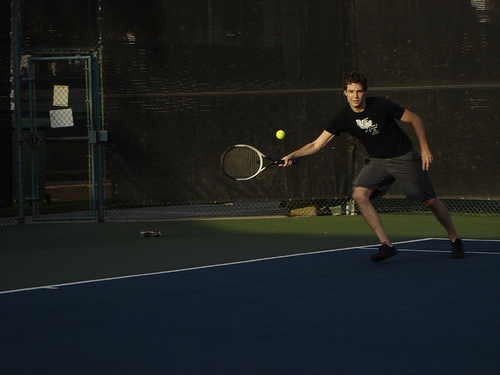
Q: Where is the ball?
A: In the air.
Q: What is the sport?
A: Tennis.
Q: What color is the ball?
A: Green.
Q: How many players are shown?
A: One.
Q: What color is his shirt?
A: Black.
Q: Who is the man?
A: A tennis player.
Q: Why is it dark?
A: Is late.